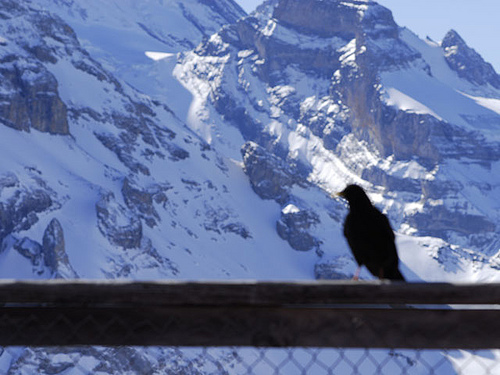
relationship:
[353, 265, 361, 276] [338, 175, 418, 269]
leg on bird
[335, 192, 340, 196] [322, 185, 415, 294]
beak on bird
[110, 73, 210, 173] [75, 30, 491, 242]
shadow on mountain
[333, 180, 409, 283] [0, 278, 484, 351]
bird standing on top of railing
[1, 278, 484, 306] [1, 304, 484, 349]
wood stacked on top of wood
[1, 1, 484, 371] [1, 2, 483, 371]
snow covering mountain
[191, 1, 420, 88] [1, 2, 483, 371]
peak jutting from mountain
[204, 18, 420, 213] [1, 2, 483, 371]
layer exposed on mountain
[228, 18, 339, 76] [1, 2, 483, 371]
layer exposed on mountain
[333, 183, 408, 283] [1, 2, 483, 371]
bird seen in front of mountain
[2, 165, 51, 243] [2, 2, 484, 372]
outcrop exposed on mountainside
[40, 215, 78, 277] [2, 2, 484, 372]
outcrop exposed on mountainside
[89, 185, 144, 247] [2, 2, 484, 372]
outcrop exposed on mountainside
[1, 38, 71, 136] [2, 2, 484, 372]
outcrop exposed on mountainside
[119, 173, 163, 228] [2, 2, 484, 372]
outcrop exposed on mountainside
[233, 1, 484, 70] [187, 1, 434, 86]
sky seen above mountain tip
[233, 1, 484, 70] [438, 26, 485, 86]
sky seen above mountain tip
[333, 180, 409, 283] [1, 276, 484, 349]
bird sitting on top of pole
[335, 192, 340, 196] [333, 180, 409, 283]
beak of bird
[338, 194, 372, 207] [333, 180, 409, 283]
neck of bird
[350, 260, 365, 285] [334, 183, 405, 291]
leg of bird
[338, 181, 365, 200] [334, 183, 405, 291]
head of bird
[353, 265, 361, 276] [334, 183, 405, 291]
leg of bird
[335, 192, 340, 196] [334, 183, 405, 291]
beak of bird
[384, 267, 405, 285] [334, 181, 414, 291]
tail of bird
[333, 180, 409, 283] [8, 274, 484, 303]
bird on ledge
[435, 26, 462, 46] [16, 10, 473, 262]
peak of mountain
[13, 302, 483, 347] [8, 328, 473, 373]
support beam for wire fencing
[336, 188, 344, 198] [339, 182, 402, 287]
beak of bird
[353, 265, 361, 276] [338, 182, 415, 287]
leg of bird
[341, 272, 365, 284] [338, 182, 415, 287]
foot of bird